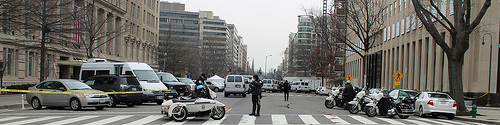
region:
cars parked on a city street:
[33, 53, 458, 121]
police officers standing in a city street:
[234, 70, 304, 120]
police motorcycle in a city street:
[150, 80, 230, 120]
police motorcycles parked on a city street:
[318, 80, 424, 115]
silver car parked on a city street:
[16, 68, 118, 113]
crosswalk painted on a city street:
[236, 107, 437, 124]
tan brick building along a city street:
[111, 1, 249, 72]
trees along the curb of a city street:
[338, 1, 490, 93]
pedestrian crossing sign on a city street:
[388, 66, 410, 93]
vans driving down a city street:
[226, 59, 281, 101]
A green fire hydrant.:
[469, 102, 479, 117]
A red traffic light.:
[228, 63, 233, 73]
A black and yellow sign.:
[391, 68, 403, 88]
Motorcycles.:
[319, 73, 416, 117]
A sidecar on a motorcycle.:
[163, 94, 224, 121]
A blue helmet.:
[194, 83, 206, 93]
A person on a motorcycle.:
[157, 81, 225, 123]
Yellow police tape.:
[1, 78, 182, 102]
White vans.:
[224, 68, 311, 97]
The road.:
[37, 67, 433, 120]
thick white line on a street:
[293, 113, 323, 124]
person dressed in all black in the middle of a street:
[241, 71, 263, 114]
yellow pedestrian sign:
[390, 68, 405, 80]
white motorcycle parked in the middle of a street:
[157, 83, 228, 120]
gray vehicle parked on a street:
[23, 77, 115, 111]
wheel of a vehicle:
[66, 96, 81, 110]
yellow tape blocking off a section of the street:
[2, 85, 177, 97]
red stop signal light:
[226, 64, 233, 71]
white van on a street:
[222, 72, 247, 98]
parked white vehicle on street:
[413, 91, 458, 118]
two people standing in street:
[240, 68, 293, 113]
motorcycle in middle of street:
[155, 82, 223, 123]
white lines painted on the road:
[7, 103, 462, 124]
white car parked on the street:
[410, 87, 453, 119]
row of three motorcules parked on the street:
[329, 81, 411, 113]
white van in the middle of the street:
[223, 71, 243, 96]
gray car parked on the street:
[21, 82, 103, 107]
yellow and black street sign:
[343, 71, 403, 84]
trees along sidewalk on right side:
[302, 6, 477, 116]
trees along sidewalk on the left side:
[5, 6, 224, 97]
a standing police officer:
[243, 72, 263, 117]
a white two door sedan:
[407, 89, 459, 120]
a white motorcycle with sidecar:
[159, 80, 228, 122]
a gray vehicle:
[82, 73, 142, 108]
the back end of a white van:
[221, 73, 248, 98]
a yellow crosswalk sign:
[390, 68, 404, 82]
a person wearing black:
[279, 80, 291, 102]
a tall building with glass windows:
[158, 0, 203, 86]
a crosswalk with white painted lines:
[0, 113, 481, 124]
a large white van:
[79, 60, 170, 104]